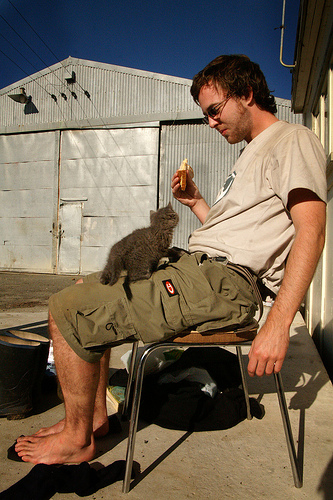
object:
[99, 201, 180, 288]
kitty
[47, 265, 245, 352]
lap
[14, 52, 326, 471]
man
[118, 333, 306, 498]
chair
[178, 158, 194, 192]
sandwich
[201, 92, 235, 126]
glasses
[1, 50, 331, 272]
building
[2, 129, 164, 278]
door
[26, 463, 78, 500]
shadow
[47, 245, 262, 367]
shorts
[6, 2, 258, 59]
sky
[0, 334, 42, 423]
boot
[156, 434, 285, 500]
ground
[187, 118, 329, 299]
shirt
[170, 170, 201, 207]
hand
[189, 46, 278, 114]
hair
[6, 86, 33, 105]
light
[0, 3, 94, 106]
wires